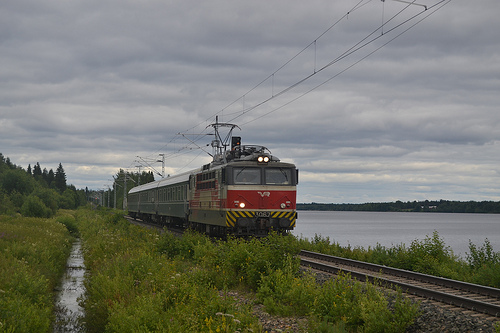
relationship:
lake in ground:
[316, 213, 498, 276] [4, 244, 470, 304]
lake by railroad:
[316, 213, 498, 276] [117, 214, 499, 330]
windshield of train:
[232, 163, 294, 188] [121, 115, 298, 236]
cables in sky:
[125, 0, 479, 169] [0, 0, 497, 199]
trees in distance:
[16, 150, 92, 215] [2, 159, 175, 194]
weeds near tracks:
[0, 205, 499, 332] [123, 211, 498, 325]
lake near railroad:
[316, 213, 498, 276] [117, 214, 499, 330]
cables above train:
[121, 0, 451, 182] [126, 135, 298, 243]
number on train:
[258, 188, 270, 200] [126, 158, 299, 230]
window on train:
[237, 163, 261, 188] [119, 141, 306, 238]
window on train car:
[261, 167, 293, 186] [187, 160, 298, 237]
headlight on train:
[238, 200, 245, 208] [124, 115, 297, 251]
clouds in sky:
[32, 56, 127, 121] [16, 20, 221, 98]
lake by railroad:
[316, 213, 498, 276] [288, 246, 498, 315]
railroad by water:
[117, 214, 499, 330] [286, 211, 496, 260]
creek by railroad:
[53, 227, 92, 329] [288, 231, 434, 316]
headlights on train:
[227, 193, 292, 210] [121, 115, 298, 236]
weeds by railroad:
[283, 230, 498, 293] [288, 246, 498, 315]